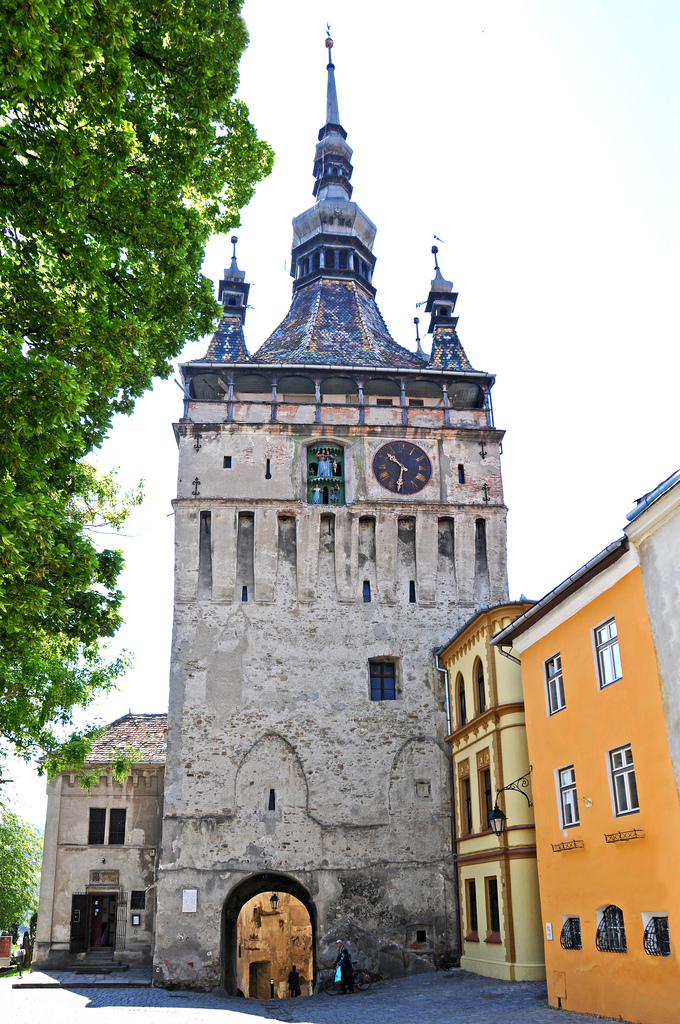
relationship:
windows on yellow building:
[540, 615, 643, 842] [520, 558, 678, 1022]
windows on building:
[448, 657, 504, 948] [431, 628, 601, 986]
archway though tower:
[211, 861, 328, 1001] [196, 78, 510, 999]